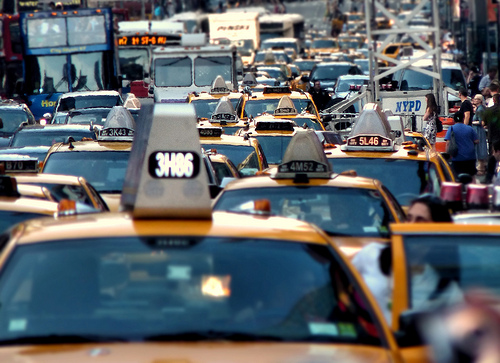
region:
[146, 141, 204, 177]
the numbers are white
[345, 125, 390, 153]
the numbers are yellow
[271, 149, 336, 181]
the numbers are blue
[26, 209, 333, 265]
the roof is yellow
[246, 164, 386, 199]
the roof is yellow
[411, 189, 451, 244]
the hair is brown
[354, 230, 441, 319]
the shirt is white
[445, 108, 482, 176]
woman holding a purse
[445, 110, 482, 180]
woman wearing a blue shirt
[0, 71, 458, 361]
yellow taxicabs on the road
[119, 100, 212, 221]
metal sign on top of taxi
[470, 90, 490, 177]
woman with light hair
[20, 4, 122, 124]
large blue mass transit bus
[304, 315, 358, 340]
sticker on the inside of a windshield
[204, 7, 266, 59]
white moving truck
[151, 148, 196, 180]
numbers and letter lit up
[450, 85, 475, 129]
man wearing black shirt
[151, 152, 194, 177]
The taxi number 3H86.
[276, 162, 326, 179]
The taxi number 4M52.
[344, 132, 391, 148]
The taxi number 5L46.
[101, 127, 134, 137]
The taxi number 3K43.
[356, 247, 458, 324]
The white shirt the lady entering the cab is wearing.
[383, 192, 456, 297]
The black hair of the lady entering the taxi.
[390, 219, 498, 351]
The open door of the taxi.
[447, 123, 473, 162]
The blue shirt the woman is wearing.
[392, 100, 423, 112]
The letters NYPD.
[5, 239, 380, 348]
The back window of the taxi numbered 3H86.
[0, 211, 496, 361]
taxi is next to taxi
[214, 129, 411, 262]
taxi is next to taxi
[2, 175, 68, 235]
taxi is next to taxi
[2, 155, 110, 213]
taxi is next to taxi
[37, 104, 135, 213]
taxi is next to taxi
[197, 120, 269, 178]
taxi is next to taxi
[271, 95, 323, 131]
taxi is next to taxi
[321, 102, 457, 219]
taxi is next to taxi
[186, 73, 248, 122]
taxi is next to taxi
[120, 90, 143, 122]
taxi is next to taxi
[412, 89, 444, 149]
woman wearing a dress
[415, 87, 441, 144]
woman carrying a black bag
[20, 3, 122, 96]
blue bus in traffic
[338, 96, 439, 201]
yellow cab with roof light on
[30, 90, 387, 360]
cab with numbers on top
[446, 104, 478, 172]
woman wearing a blue shirt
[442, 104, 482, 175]
woman carrying gray purse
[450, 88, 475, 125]
man wearing black t-shirt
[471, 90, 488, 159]
woman wearing blue jean dress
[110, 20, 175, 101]
bus with numbers on the front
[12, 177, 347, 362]
this is a car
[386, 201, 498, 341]
this is a car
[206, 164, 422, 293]
this is a car